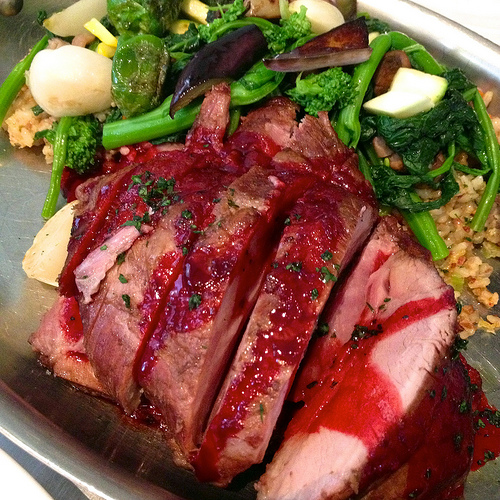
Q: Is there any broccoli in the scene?
A: Yes, there is broccoli.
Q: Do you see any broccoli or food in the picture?
A: Yes, there is broccoli.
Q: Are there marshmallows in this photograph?
A: No, there are no marshmallows.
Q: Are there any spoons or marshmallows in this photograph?
A: No, there are no marshmallows or spoons.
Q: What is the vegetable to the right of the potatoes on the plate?
A: The vegetable is broccoli.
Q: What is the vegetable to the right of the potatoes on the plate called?
A: The vegetable is broccoli.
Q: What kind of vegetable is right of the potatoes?
A: The vegetable is broccoli.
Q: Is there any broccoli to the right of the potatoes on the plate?
A: Yes, there is broccoli to the right of the potatoes.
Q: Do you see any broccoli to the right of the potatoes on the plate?
A: Yes, there is broccoli to the right of the potatoes.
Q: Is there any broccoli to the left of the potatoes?
A: No, the broccoli is to the right of the potatoes.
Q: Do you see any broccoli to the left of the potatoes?
A: No, the broccoli is to the right of the potatoes.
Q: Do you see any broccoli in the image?
A: Yes, there is broccoli.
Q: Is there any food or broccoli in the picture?
A: Yes, there is broccoli.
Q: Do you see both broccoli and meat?
A: Yes, there are both broccoli and meat.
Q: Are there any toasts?
A: No, there are no toasts.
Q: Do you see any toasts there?
A: No, there are no toasts.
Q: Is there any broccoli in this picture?
A: Yes, there is broccoli.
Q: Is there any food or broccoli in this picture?
A: Yes, there is broccoli.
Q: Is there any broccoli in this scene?
A: Yes, there is broccoli.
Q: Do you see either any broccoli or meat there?
A: Yes, there is broccoli.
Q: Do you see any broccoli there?
A: Yes, there is broccoli.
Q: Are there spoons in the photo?
A: No, there are no spoons.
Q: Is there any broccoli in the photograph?
A: Yes, there is broccoli.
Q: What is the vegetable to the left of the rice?
A: The vegetable is broccoli.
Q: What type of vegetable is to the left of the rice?
A: The vegetable is broccoli.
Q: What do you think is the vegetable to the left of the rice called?
A: The vegetable is broccoli.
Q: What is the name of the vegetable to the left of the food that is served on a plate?
A: The vegetable is broccoli.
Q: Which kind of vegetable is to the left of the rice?
A: The vegetable is broccoli.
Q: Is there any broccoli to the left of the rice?
A: Yes, there is broccoli to the left of the rice.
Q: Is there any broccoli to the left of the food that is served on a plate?
A: Yes, there is broccoli to the left of the rice.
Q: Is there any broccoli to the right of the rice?
A: No, the broccoli is to the left of the rice.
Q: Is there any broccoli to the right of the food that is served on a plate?
A: No, the broccoli is to the left of the rice.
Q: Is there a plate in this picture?
A: Yes, there is a plate.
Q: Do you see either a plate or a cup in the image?
A: Yes, there is a plate.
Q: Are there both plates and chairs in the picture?
A: No, there is a plate but no chairs.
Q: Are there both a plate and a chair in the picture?
A: No, there is a plate but no chairs.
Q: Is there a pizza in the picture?
A: No, there are no pizzas.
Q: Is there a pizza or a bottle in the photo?
A: No, there are no pizzas or bottles.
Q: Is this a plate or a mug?
A: This is a plate.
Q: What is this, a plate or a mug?
A: This is a plate.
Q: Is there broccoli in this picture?
A: Yes, there is broccoli.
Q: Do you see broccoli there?
A: Yes, there is broccoli.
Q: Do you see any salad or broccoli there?
A: Yes, there is broccoli.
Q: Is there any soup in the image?
A: No, there is no soup.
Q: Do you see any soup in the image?
A: No, there is no soup.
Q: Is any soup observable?
A: No, there is no soup.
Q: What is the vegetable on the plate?
A: The vegetable is broccoli.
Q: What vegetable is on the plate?
A: The vegetable is broccoli.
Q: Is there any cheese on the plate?
A: No, there is broccoli on the plate.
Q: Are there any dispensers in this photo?
A: No, there are no dispensers.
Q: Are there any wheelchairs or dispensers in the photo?
A: No, there are no dispensers or wheelchairs.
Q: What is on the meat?
A: The blood is on the meat.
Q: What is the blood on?
A: The blood is on the meat.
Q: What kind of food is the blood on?
A: The blood is on the meat.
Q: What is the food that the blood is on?
A: The food is meat.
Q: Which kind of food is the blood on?
A: The blood is on the meat.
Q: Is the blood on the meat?
A: Yes, the blood is on the meat.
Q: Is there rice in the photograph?
A: Yes, there is rice.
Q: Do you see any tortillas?
A: No, there are no tortillas.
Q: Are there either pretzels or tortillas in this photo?
A: No, there are no tortillas or pretzels.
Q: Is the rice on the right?
A: Yes, the rice is on the right of the image.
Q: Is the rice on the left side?
A: No, the rice is on the right of the image.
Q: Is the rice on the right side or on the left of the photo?
A: The rice is on the right of the image.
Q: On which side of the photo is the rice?
A: The rice is on the right of the image.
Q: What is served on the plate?
A: The rice is served on the plate.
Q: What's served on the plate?
A: The rice is served on the plate.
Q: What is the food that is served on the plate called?
A: The food is rice.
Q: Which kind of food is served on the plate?
A: The food is rice.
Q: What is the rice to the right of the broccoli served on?
A: The rice is served on a plate.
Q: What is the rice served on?
A: The rice is served on a plate.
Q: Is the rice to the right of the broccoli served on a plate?
A: Yes, the rice is served on a plate.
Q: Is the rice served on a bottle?
A: No, the rice is served on a plate.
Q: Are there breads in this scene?
A: No, there are no breads.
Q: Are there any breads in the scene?
A: No, there are no breads.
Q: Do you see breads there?
A: No, there are no breads.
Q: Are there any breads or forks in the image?
A: No, there are no breads or forks.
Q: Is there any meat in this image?
A: Yes, there is meat.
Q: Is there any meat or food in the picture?
A: Yes, there is meat.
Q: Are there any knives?
A: No, there are no knives.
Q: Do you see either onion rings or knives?
A: No, there are no knives or onion rings.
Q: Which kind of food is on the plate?
A: The food is meat.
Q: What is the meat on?
A: The meat is on the plate.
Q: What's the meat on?
A: The meat is on the plate.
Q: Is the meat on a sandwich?
A: No, the meat is on the plate.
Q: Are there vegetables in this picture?
A: Yes, there are vegetables.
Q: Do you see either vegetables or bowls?
A: Yes, there are vegetables.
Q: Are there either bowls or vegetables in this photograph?
A: Yes, there are vegetables.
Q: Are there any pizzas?
A: No, there are no pizzas.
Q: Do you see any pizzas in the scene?
A: No, there are no pizzas.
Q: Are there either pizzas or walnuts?
A: No, there are no pizzas or walnuts.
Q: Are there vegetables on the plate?
A: Yes, there are vegetables on the plate.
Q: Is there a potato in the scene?
A: Yes, there are potatoes.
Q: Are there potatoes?
A: Yes, there are potatoes.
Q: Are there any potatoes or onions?
A: Yes, there are potatoes.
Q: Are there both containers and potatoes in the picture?
A: No, there are potatoes but no containers.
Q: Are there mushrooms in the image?
A: No, there are no mushrooms.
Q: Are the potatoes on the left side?
A: Yes, the potatoes are on the left of the image.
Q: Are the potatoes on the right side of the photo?
A: No, the potatoes are on the left of the image.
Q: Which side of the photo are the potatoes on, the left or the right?
A: The potatoes are on the left of the image.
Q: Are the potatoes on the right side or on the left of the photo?
A: The potatoes are on the left of the image.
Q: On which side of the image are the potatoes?
A: The potatoes are on the left of the image.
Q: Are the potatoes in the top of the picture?
A: Yes, the potatoes are in the top of the image.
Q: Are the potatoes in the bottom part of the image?
A: No, the potatoes are in the top of the image.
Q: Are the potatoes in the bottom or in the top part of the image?
A: The potatoes are in the top of the image.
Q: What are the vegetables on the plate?
A: The vegetables are potatoes.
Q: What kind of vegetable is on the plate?
A: The vegetables are potatoes.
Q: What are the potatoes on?
A: The potatoes are on the plate.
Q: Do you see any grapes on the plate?
A: No, there are potatoes on the plate.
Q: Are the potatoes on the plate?
A: Yes, the potatoes are on the plate.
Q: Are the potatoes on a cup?
A: No, the potatoes are on the plate.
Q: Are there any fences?
A: No, there are no fences.